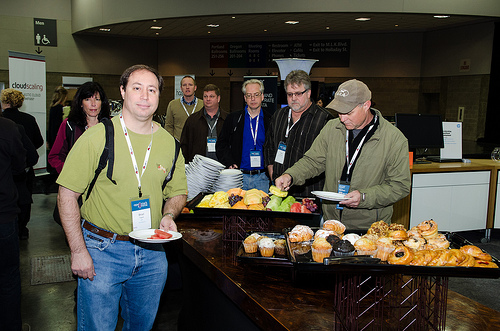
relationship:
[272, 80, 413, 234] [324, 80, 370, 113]
man has cap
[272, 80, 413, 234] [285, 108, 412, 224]
man has coat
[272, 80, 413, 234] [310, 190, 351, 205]
man has plate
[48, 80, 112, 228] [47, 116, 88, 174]
lady wearing shirt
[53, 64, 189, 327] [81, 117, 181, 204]
man wearing backpack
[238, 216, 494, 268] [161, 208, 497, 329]
pastries on table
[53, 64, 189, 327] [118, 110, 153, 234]
man wearing badge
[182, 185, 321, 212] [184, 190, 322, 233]
fruit in tray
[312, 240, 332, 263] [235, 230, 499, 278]
muffin on plate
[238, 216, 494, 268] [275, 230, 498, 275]
pastries on tray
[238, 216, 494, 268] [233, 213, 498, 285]
pastries on tray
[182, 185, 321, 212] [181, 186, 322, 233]
fruit in container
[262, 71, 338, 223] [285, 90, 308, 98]
man wearing glasses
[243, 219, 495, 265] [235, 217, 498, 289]
pastry on tray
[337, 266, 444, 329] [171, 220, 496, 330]
crate on table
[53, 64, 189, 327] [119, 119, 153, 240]
man has badge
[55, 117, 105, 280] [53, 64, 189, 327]
arm of man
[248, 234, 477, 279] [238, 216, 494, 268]
plate of pastries